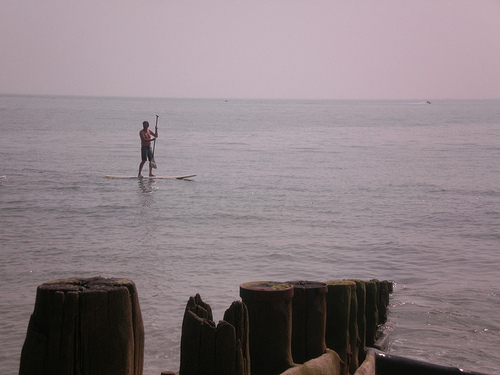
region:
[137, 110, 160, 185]
A man on a surfboard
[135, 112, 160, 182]
The man is standing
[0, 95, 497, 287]
Calm grey water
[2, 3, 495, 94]
A foggy grey ocean sky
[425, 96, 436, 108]
A seabird far away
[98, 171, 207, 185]
A surfboard in the water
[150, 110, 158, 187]
A paddle the man is using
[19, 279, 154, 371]
An old wooden post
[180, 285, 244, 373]
A broken wooden post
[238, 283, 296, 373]
Another old wooden post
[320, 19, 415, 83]
part of the sky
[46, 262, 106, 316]
edge of a trunk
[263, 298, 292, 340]
part of a trunk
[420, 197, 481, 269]
part of a water body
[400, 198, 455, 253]
part of a water body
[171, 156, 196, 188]
part of a swimming board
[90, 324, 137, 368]
edge of a trunk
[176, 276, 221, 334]
part of a trunk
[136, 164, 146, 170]
part of a leg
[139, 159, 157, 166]
part of a knee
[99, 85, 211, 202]
the man is on a surfboard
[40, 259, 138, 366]
the posts of the pier are wood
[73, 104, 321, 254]
the sea is too calm for surfing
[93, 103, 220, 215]
the man appears to be poling his surfboard around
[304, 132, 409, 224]
the sea is grey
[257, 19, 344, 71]
the sky is cloudy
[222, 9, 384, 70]
the sky is grey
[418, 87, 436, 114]
a boat is in the background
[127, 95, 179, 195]
the man is not wearing a shirt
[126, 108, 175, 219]
the man appears to be wearing shorts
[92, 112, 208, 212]
one man in water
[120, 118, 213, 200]
one man holding a stick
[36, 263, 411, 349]
pier leading into water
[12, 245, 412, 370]
nine logs visible out of water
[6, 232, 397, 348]
one broken log in picture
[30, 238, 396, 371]
eight rounded top logs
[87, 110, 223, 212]
man not wearing shirt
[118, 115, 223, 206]
man in water alone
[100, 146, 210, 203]
board in water with man on it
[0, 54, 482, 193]
nothing on horizon in background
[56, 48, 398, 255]
man floating on board in ocean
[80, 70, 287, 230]
man floating on board in sea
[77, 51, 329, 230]
man in the ocean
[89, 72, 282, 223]
man in the sea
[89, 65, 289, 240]
man on board with stick in ocean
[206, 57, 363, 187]
horizon where sky meets water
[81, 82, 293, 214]
calm ocean waters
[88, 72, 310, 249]
man floating in indian ocean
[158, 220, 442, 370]
pier leading into ocean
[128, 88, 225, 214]
man with no shirt in ocean